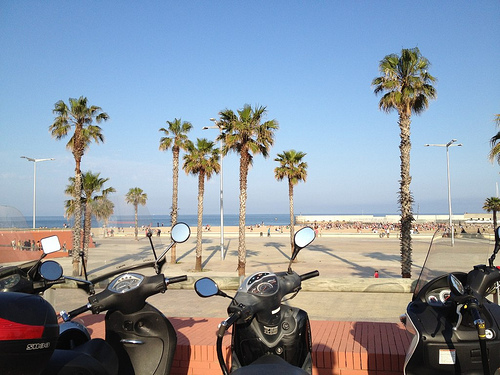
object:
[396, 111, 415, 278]
tree trunk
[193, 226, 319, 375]
motorbike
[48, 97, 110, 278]
palm tree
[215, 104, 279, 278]
palm tree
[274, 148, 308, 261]
palm tree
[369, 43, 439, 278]
palm tree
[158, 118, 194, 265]
palm tree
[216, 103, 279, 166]
fronds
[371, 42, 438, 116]
fronds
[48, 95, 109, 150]
fronds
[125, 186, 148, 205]
fronds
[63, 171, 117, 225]
fronds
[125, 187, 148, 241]
tree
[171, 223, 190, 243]
mirror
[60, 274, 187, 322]
handlebars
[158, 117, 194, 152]
leaves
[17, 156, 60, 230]
lamp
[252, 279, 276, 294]
speedometer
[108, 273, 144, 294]
dashboard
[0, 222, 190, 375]
motorbike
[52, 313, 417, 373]
brick wall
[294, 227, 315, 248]
mirror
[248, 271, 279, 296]
gauge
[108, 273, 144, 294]
gauge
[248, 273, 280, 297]
dashboard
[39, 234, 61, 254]
mirror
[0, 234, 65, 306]
scooter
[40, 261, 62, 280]
mirror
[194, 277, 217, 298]
mirror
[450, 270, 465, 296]
mirror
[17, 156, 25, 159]
light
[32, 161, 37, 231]
post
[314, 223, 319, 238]
person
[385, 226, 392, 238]
person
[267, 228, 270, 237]
person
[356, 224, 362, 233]
person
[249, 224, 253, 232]
person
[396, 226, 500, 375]
motorbike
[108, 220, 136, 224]
green grass